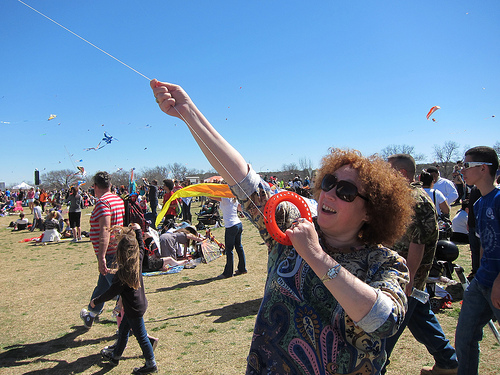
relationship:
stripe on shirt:
[94, 200, 125, 216] [89, 187, 131, 262]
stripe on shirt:
[93, 209, 118, 225] [89, 187, 131, 262]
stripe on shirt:
[106, 217, 118, 224] [89, 187, 131, 262]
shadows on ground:
[0, 272, 262, 373] [0, 202, 498, 373]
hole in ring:
[275, 199, 305, 231] [262, 182, 315, 251]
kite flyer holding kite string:
[150, 77, 415, 374] [16, 0, 273, 223]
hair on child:
[105, 224, 143, 290] [89, 222, 158, 374]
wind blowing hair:
[70, 145, 101, 170] [105, 224, 143, 290]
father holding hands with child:
[75, 171, 122, 326] [89, 222, 158, 374]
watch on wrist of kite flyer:
[312, 255, 354, 304] [207, 132, 423, 351]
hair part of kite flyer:
[312, 145, 417, 248] [150, 77, 415, 374]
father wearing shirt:
[80, 171, 160, 357] [88, 191, 125, 255]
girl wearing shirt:
[210, 182, 248, 277] [218, 192, 236, 229]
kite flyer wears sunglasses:
[150, 77, 415, 374] [317, 170, 370, 203]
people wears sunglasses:
[62, 185, 87, 244] [458, 160, 492, 169]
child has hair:
[89, 222, 158, 374] [118, 236, 141, 293]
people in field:
[5, 183, 245, 269] [0, 187, 498, 374]